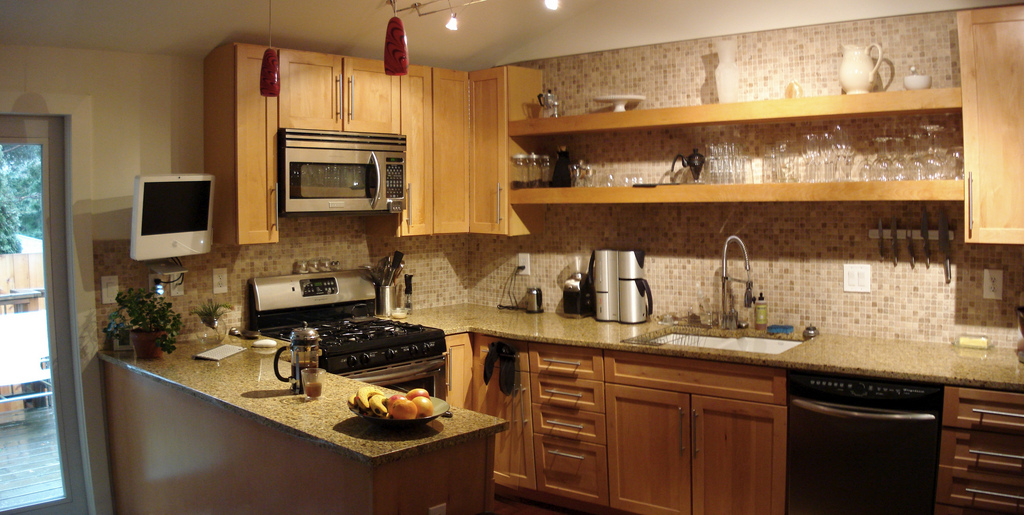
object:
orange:
[384, 394, 417, 420]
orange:
[413, 392, 440, 419]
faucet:
[714, 230, 757, 330]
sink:
[636, 323, 808, 362]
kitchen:
[3, 3, 992, 511]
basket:
[340, 387, 457, 429]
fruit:
[389, 394, 421, 421]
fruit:
[406, 390, 433, 416]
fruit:
[403, 379, 431, 399]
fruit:
[365, 392, 392, 419]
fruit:
[353, 383, 436, 419]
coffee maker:
[581, 243, 657, 328]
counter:
[389, 299, 994, 392]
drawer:
[532, 374, 604, 414]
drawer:
[528, 398, 608, 446]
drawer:
[526, 424, 609, 505]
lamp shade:
[380, 16, 412, 81]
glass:
[918, 108, 951, 175]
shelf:
[485, 4, 1021, 264]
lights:
[435, 6, 470, 43]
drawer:
[532, 351, 600, 395]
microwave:
[273, 122, 405, 222]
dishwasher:
[767, 357, 923, 509]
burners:
[274, 317, 452, 380]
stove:
[228, 261, 458, 409]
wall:
[87, 84, 172, 169]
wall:
[662, 255, 706, 310]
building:
[6, 10, 1017, 508]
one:
[265, 107, 415, 278]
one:
[255, 265, 453, 406]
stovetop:
[329, 287, 372, 348]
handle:
[777, 405, 938, 427]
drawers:
[240, 77, 507, 236]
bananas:
[347, 386, 391, 417]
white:
[820, 264, 887, 299]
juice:
[283, 327, 336, 399]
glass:
[290, 356, 317, 383]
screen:
[91, 131, 252, 317]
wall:
[72, 246, 108, 324]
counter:
[147, 332, 509, 471]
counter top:
[452, 322, 682, 351]